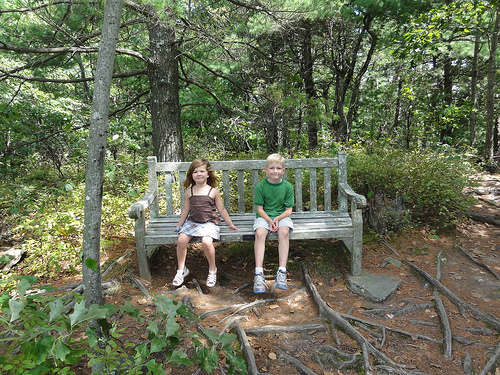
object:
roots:
[0, 210, 500, 373]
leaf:
[69, 298, 88, 326]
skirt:
[175, 221, 219, 241]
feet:
[251, 266, 268, 292]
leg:
[350, 209, 363, 276]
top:
[187, 185, 217, 223]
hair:
[265, 153, 285, 168]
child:
[172, 158, 239, 287]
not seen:
[6, 23, 498, 362]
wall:
[249, 114, 299, 146]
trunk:
[81, 0, 123, 364]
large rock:
[346, 272, 403, 303]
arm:
[338, 182, 367, 209]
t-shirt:
[253, 177, 294, 219]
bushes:
[209, 137, 487, 240]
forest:
[0, 0, 499, 375]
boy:
[252, 153, 294, 294]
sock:
[255, 267, 264, 277]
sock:
[278, 266, 287, 271]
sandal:
[206, 267, 218, 287]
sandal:
[172, 266, 190, 285]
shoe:
[274, 269, 289, 291]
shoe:
[252, 271, 268, 293]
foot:
[275, 268, 288, 290]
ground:
[0, 160, 500, 375]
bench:
[128, 151, 368, 281]